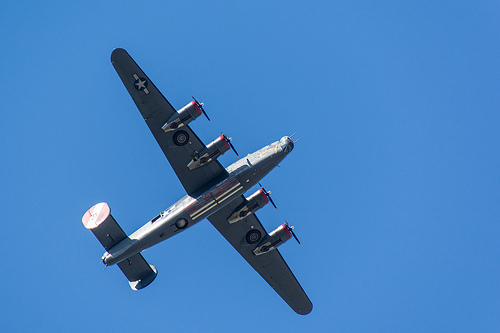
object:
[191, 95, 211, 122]
propeller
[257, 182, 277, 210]
propeller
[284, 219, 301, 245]
propeller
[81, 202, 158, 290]
tail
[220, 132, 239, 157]
propeller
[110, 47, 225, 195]
plane wing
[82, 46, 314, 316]
jet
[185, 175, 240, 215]
logo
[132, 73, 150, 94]
logo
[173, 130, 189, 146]
logo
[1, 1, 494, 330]
sky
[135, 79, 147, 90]
star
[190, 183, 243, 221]
stripe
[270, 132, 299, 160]
front